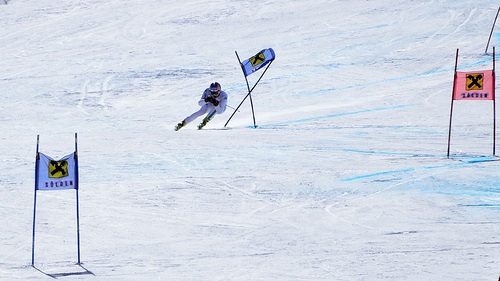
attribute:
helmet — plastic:
[207, 80, 224, 93]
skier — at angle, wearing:
[173, 82, 235, 135]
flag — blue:
[237, 43, 278, 83]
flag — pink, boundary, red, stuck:
[450, 67, 493, 104]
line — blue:
[301, 57, 499, 99]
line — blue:
[258, 99, 432, 131]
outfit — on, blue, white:
[185, 90, 231, 128]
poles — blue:
[225, 51, 274, 130]